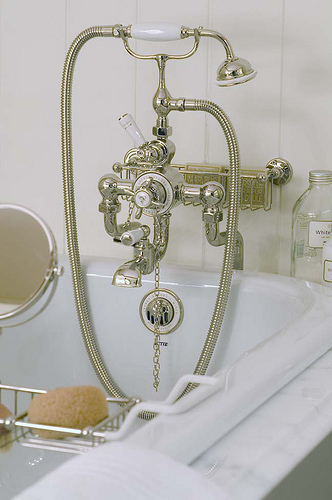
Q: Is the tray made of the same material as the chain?
A: Yes, both the tray and the chain are made of metal.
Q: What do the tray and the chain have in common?
A: The material, both the tray and the chain are metallic.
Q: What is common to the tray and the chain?
A: The material, both the tray and the chain are metallic.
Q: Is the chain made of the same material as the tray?
A: Yes, both the chain and the tray are made of metal.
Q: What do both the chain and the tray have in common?
A: The material, both the chain and the tray are metallic.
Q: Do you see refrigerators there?
A: No, there are no refrigerators.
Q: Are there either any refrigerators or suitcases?
A: No, there are no refrigerators or suitcases.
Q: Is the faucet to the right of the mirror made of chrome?
A: Yes, the tap is made of chrome.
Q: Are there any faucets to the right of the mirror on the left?
A: Yes, there is a faucet to the right of the mirror.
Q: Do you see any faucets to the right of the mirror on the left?
A: Yes, there is a faucet to the right of the mirror.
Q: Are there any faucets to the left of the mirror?
A: No, the faucet is to the right of the mirror.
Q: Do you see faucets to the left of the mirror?
A: No, the faucet is to the right of the mirror.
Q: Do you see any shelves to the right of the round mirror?
A: No, there is a faucet to the right of the mirror.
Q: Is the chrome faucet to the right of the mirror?
A: Yes, the faucet is to the right of the mirror.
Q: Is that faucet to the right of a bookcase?
A: No, the faucet is to the right of the mirror.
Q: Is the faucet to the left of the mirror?
A: No, the faucet is to the right of the mirror.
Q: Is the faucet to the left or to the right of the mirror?
A: The faucet is to the right of the mirror.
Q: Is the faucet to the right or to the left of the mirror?
A: The faucet is to the right of the mirror.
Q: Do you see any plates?
A: No, there are no plates.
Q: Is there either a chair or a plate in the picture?
A: No, there are no plates or chairs.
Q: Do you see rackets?
A: No, there are no rackets.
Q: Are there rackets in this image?
A: No, there are no rackets.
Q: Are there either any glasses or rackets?
A: No, there are no rackets or glasses.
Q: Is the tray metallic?
A: Yes, the tray is metallic.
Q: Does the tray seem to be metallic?
A: Yes, the tray is metallic.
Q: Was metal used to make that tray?
A: Yes, the tray is made of metal.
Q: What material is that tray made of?
A: The tray is made of metal.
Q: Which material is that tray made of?
A: The tray is made of metal.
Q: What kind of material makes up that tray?
A: The tray is made of metal.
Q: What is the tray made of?
A: The tray is made of metal.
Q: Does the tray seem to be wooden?
A: No, the tray is metallic.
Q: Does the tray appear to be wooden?
A: No, the tray is metallic.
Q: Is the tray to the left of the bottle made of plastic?
A: No, the tray is made of metal.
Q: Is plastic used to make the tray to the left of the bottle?
A: No, the tray is made of metal.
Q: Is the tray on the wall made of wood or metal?
A: The tray is made of metal.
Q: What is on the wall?
A: The tray is on the wall.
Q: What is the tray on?
A: The tray is on the wall.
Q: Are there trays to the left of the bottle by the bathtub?
A: Yes, there is a tray to the left of the bottle.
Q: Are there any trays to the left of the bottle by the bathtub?
A: Yes, there is a tray to the left of the bottle.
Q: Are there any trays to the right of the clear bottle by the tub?
A: No, the tray is to the left of the bottle.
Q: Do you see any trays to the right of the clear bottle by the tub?
A: No, the tray is to the left of the bottle.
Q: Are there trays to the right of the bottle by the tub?
A: No, the tray is to the left of the bottle.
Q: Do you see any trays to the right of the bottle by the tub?
A: No, the tray is to the left of the bottle.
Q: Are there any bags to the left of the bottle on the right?
A: No, there is a tray to the left of the bottle.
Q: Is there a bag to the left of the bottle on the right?
A: No, there is a tray to the left of the bottle.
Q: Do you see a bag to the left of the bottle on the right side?
A: No, there is a tray to the left of the bottle.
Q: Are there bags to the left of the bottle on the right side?
A: No, there is a tray to the left of the bottle.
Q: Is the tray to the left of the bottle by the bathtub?
A: Yes, the tray is to the left of the bottle.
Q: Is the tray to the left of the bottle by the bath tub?
A: Yes, the tray is to the left of the bottle.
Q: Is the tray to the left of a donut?
A: No, the tray is to the left of the bottle.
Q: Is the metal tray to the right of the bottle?
A: No, the tray is to the left of the bottle.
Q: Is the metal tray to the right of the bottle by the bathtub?
A: No, the tray is to the left of the bottle.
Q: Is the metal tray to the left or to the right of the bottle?
A: The tray is to the left of the bottle.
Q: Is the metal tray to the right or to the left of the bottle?
A: The tray is to the left of the bottle.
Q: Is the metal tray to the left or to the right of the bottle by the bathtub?
A: The tray is to the left of the bottle.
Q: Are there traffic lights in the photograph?
A: No, there are no traffic lights.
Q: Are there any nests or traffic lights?
A: No, there are no traffic lights or nests.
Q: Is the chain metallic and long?
A: Yes, the chain is metallic and long.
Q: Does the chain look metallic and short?
A: No, the chain is metallic but long.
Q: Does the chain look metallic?
A: Yes, the chain is metallic.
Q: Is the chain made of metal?
A: Yes, the chain is made of metal.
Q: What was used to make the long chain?
A: The chain is made of metal.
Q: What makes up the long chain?
A: The chain is made of metal.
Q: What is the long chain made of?
A: The chain is made of metal.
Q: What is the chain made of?
A: The chain is made of metal.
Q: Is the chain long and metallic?
A: Yes, the chain is long and metallic.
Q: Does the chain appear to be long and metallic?
A: Yes, the chain is long and metallic.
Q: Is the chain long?
A: Yes, the chain is long.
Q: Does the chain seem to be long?
A: Yes, the chain is long.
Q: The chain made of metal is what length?
A: The chain is long.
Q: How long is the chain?
A: The chain is long.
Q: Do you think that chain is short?
A: No, the chain is long.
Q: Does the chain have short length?
A: No, the chain is long.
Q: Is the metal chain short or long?
A: The chain is long.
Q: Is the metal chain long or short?
A: The chain is long.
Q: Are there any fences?
A: No, there are no fences.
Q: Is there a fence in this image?
A: No, there are no fences.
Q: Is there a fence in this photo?
A: No, there are no fences.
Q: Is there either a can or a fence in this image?
A: No, there are no fences or cans.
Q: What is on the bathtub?
A: The drain is on the bath tub.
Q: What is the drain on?
A: The drain is on the bathtub.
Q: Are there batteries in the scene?
A: No, there are no batteries.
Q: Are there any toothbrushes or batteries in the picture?
A: No, there are no batteries or toothbrushes.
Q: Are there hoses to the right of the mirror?
A: Yes, there is a hose to the right of the mirror.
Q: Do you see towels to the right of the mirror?
A: No, there is a hose to the right of the mirror.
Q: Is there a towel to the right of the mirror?
A: No, there is a hose to the right of the mirror.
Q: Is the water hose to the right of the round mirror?
A: Yes, the water hose is to the right of the mirror.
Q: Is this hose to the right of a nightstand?
A: No, the hose is to the right of the mirror.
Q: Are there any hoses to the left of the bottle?
A: Yes, there is a hose to the left of the bottle.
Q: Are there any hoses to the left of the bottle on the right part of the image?
A: Yes, there is a hose to the left of the bottle.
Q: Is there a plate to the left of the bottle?
A: No, there is a hose to the left of the bottle.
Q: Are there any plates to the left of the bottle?
A: No, there is a hose to the left of the bottle.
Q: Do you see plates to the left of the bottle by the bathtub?
A: No, there is a hose to the left of the bottle.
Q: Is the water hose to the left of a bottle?
A: Yes, the water hose is to the left of a bottle.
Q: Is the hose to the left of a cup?
A: No, the hose is to the left of a bottle.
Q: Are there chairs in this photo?
A: No, there are no chairs.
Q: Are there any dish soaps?
A: No, there are no dish soaps.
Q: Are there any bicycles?
A: No, there are no bicycles.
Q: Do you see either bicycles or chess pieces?
A: No, there are no bicycles or chess pieces.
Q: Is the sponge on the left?
A: Yes, the sponge is on the left of the image.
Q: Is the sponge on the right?
A: No, the sponge is on the left of the image.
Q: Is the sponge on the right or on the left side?
A: The sponge is on the left of the image.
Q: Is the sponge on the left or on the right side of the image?
A: The sponge is on the left of the image.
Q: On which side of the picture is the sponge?
A: The sponge is on the left of the image.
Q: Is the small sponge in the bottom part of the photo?
A: Yes, the sponge is in the bottom of the image.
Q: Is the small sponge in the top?
A: No, the sponge is in the bottom of the image.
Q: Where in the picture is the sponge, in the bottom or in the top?
A: The sponge is in the bottom of the image.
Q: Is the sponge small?
A: Yes, the sponge is small.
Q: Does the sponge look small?
A: Yes, the sponge is small.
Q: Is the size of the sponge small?
A: Yes, the sponge is small.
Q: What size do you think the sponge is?
A: The sponge is small.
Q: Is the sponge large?
A: No, the sponge is small.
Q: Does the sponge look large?
A: No, the sponge is small.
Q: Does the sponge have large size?
A: No, the sponge is small.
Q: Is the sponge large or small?
A: The sponge is small.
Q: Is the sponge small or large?
A: The sponge is small.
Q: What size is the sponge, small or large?
A: The sponge is small.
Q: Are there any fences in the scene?
A: No, there are no fences.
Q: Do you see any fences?
A: No, there are no fences.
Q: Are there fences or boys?
A: No, there are no fences or boys.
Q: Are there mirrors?
A: Yes, there is a mirror.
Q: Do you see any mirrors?
A: Yes, there is a mirror.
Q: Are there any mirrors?
A: Yes, there is a mirror.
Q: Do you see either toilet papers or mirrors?
A: Yes, there is a mirror.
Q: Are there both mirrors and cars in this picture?
A: No, there is a mirror but no cars.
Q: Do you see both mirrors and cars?
A: No, there is a mirror but no cars.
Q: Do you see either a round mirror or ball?
A: Yes, there is a round mirror.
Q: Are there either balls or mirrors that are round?
A: Yes, the mirror is round.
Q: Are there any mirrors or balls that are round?
A: Yes, the mirror is round.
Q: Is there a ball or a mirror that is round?
A: Yes, the mirror is round.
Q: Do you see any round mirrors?
A: Yes, there is a round mirror.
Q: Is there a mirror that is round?
A: Yes, there is a mirror that is round.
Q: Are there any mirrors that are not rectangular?
A: Yes, there is a round mirror.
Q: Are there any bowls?
A: No, there are no bowls.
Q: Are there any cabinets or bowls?
A: No, there are no bowls or cabinets.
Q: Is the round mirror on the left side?
A: Yes, the mirror is on the left of the image.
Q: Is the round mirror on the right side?
A: No, the mirror is on the left of the image.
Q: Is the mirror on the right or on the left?
A: The mirror is on the left of the image.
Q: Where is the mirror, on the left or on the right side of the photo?
A: The mirror is on the left of the image.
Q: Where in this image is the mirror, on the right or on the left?
A: The mirror is on the left of the image.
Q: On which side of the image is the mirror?
A: The mirror is on the left of the image.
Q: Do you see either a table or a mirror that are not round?
A: No, there is a mirror but it is round.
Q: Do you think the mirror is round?
A: Yes, the mirror is round.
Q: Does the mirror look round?
A: Yes, the mirror is round.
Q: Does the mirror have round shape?
A: Yes, the mirror is round.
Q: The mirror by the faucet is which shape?
A: The mirror is round.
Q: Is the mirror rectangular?
A: No, the mirror is round.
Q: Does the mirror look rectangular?
A: No, the mirror is round.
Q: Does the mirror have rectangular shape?
A: No, the mirror is round.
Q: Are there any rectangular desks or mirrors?
A: No, there is a mirror but it is round.